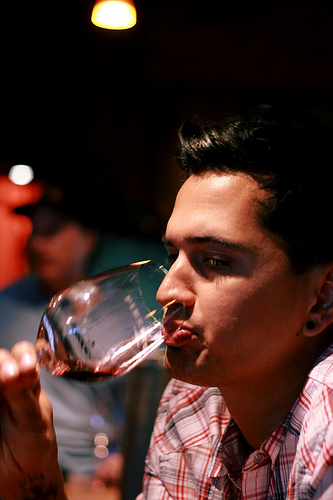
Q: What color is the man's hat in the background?
A: Black.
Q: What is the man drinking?
A: Wine.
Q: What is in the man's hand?
A: Glass.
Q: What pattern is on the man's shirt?
A: Striped.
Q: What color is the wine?
A: Red.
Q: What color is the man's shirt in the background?
A: Blue.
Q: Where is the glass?
A: Mouth.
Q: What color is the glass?
A: Clear.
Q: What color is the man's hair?
A: Black.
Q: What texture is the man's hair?
A: Straight.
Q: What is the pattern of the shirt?
A: Plaid.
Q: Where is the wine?
A: In the glass.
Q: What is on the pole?
A: A light.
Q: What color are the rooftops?
A: Green.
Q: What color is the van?
A: Black.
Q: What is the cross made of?
A: Gold.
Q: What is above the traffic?
A: Wires.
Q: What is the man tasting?
A: Wine.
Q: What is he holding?
A: Wine Glass.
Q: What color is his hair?
A: Black.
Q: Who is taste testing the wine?
A: A man.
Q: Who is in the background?
A: A man with a hat.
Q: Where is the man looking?
A: In the wineglass.